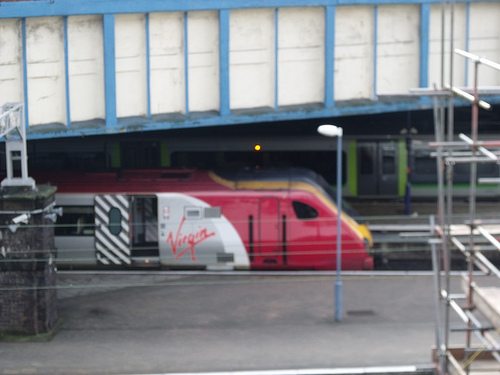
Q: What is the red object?
A: Train.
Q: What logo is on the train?
A: Virgin.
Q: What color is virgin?
A: Red.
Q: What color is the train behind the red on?
A: Green/white.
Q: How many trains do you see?
A: Two.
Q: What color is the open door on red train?
A: Black/white.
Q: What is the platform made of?
A: Concrete.